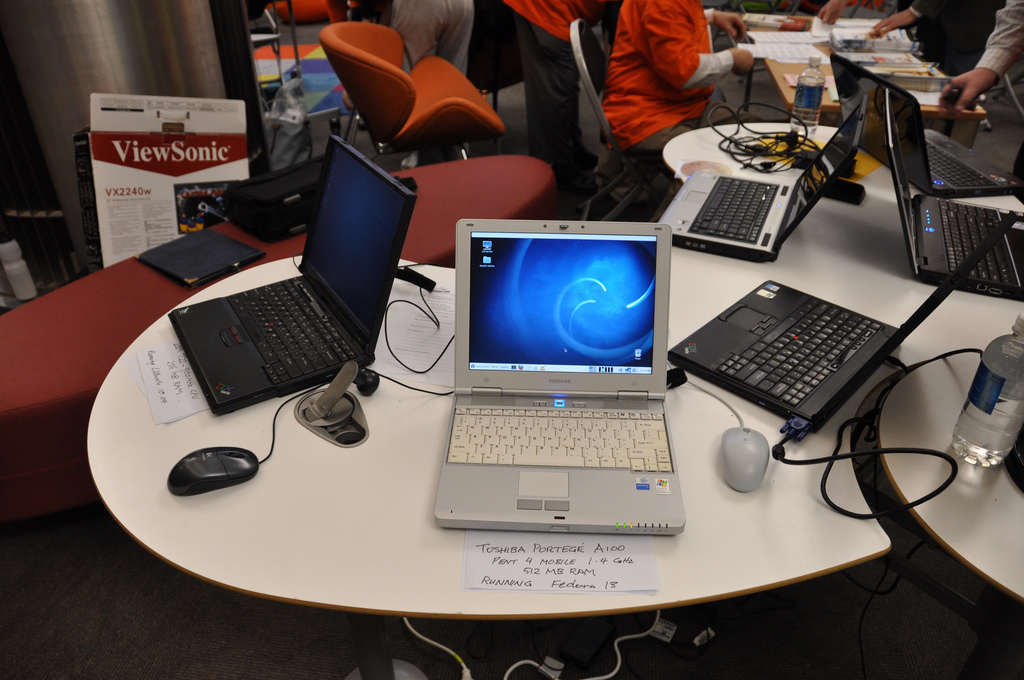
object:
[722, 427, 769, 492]
mouse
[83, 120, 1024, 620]
desk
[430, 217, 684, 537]
computer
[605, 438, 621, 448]
button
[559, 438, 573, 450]
button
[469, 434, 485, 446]
button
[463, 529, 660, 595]
paper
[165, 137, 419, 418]
laptop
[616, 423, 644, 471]
button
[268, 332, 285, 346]
button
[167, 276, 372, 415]
keyboard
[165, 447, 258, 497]
mouse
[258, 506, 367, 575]
desk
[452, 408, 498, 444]
button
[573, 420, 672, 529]
button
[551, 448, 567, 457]
button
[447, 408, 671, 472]
keyboard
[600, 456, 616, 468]
button